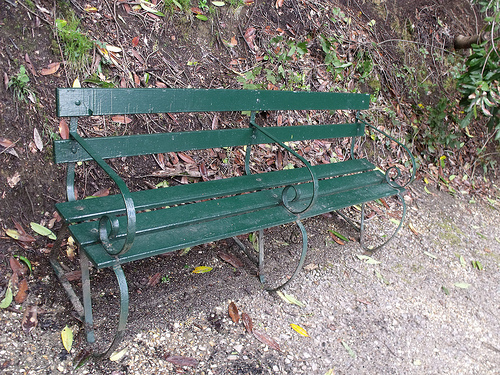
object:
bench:
[55, 84, 414, 357]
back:
[54, 88, 369, 198]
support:
[87, 266, 129, 361]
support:
[267, 220, 310, 292]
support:
[365, 195, 407, 253]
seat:
[50, 158, 405, 266]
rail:
[55, 87, 370, 111]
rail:
[54, 124, 365, 164]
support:
[45, 220, 96, 345]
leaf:
[31, 220, 57, 240]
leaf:
[113, 115, 132, 125]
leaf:
[20, 48, 45, 80]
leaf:
[179, 151, 195, 165]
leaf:
[33, 128, 43, 154]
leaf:
[192, 265, 213, 275]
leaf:
[290, 320, 309, 337]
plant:
[425, 101, 466, 172]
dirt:
[0, 2, 499, 303]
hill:
[0, 0, 499, 307]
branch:
[455, 1, 499, 126]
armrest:
[70, 132, 136, 257]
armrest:
[251, 121, 319, 214]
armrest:
[358, 118, 417, 189]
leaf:
[0, 286, 16, 310]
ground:
[0, 176, 497, 374]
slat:
[76, 179, 406, 270]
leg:
[79, 252, 132, 360]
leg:
[258, 221, 306, 293]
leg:
[358, 194, 405, 252]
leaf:
[242, 312, 280, 351]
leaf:
[328, 229, 345, 246]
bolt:
[75, 100, 82, 105]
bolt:
[72, 148, 79, 154]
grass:
[417, 98, 449, 132]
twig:
[49, 1, 72, 86]